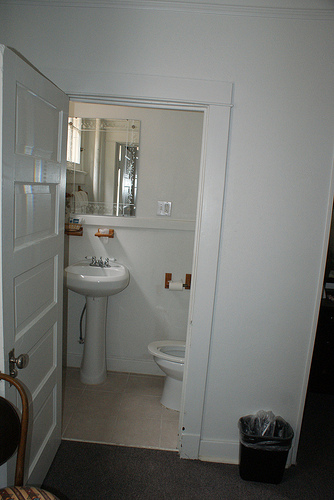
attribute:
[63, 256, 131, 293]
sink — white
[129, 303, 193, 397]
toilet seat — white, plastic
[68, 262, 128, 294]
sink — porcelain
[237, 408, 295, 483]
garbage can — black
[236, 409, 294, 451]
bag — plastic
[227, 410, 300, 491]
garbage — clear, can, liner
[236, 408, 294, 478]
basket — waste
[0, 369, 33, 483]
back — rounded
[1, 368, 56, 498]
chair — wooden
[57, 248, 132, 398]
sink — bathroom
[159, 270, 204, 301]
paper roll — toilet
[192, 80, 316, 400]
wall — white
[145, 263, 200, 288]
roll — toilet paper holding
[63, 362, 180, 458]
floor — tile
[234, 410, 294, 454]
liner — plastic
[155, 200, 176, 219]
outlet — electrical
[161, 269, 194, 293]
dispenser — brown, wooden, toilet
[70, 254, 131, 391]
sink — white, pedastal, bathroom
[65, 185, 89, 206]
towel rack — wooden